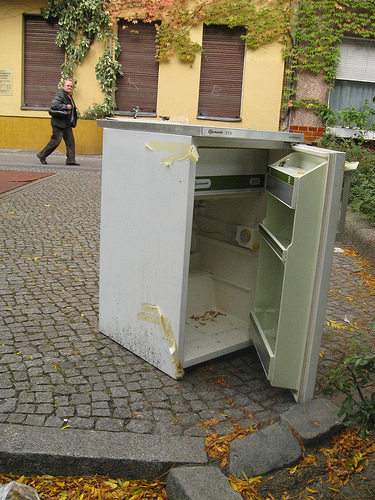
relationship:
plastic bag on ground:
[4, 481, 40, 498] [0, 469, 163, 499]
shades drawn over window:
[198, 22, 240, 115] [198, 25, 243, 121]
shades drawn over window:
[114, 18, 156, 113] [113, 12, 159, 113]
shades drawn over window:
[24, 14, 64, 108] [19, 11, 70, 110]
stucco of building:
[2, 5, 291, 129] [1, 3, 290, 165]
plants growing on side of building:
[40, 6, 355, 97] [4, 2, 354, 156]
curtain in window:
[324, 79, 373, 136] [325, 48, 373, 136]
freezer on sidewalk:
[95, 119, 359, 405] [18, 196, 95, 426]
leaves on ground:
[31, 477, 166, 497] [3, 154, 371, 462]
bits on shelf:
[191, 309, 221, 326] [199, 272, 230, 299]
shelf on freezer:
[199, 272, 230, 299] [95, 119, 359, 405]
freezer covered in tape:
[95, 119, 359, 405] [137, 301, 186, 376]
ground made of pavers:
[1, 153, 373, 498] [12, 289, 104, 382]